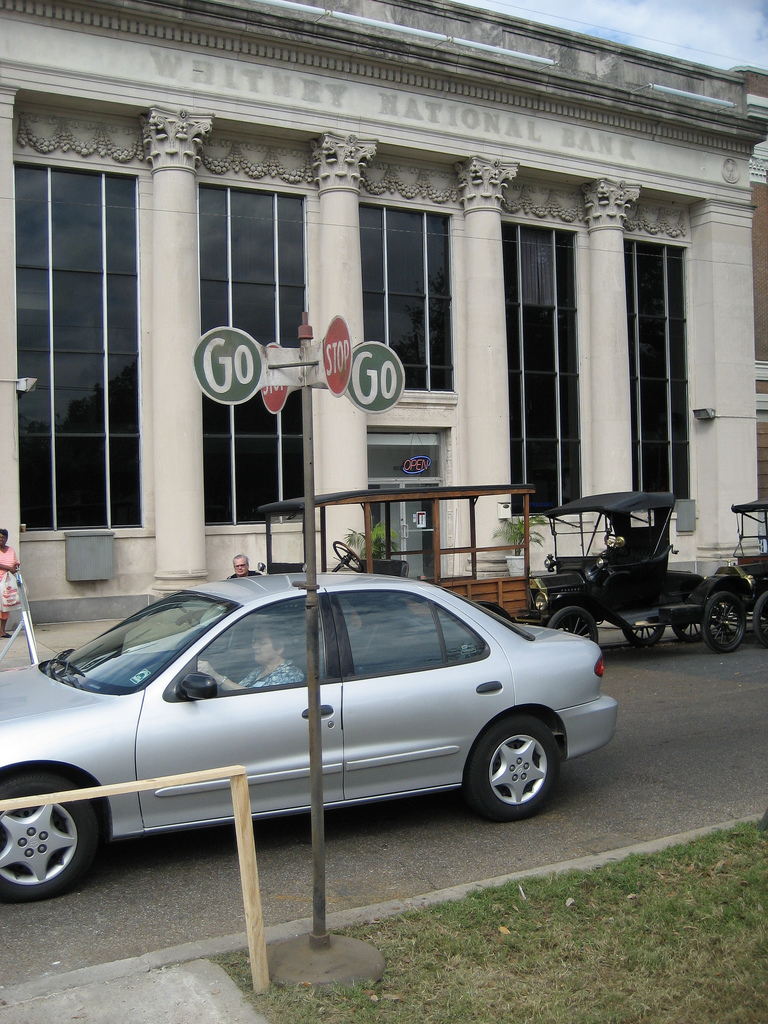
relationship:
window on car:
[437, 601, 490, 673] [9, 569, 641, 901]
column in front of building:
[448, 168, 541, 572] [7, 7, 766, 639]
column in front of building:
[578, 183, 656, 547] [7, 7, 766, 639]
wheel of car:
[4, 764, 110, 900] [9, 569, 641, 901]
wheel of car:
[475, 698, 569, 818] [7, 564, 626, 924]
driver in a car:
[190, 617, 328, 700] [4, 559, 586, 901]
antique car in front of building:
[542, 469, 683, 608] [61, 340, 640, 651]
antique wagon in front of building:
[300, 483, 551, 607] [86, 240, 624, 403]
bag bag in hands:
[1, 516, 44, 704] [3, 443, 90, 708]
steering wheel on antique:
[317, 531, 371, 568] [253, 484, 537, 619]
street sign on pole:
[325, 333, 376, 380] [293, 471, 327, 574]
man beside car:
[208, 555, 273, 596] [38, 619, 546, 901]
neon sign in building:
[387, 442, 458, 485] [0, 0, 766, 622]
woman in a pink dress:
[0, 510, 41, 639] [1, 543, 14, 575]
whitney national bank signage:
[145, 81, 636, 159] [260, 154, 516, 264]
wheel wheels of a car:
[463, 710, 561, 822] [5, 690, 503, 895]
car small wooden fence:
[0, 573, 618, 901] [218, 849, 273, 948]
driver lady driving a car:
[197, 611, 305, 691] [7, 592, 532, 922]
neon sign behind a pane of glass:
[402, 455, 432, 475] [353, 423, 449, 485]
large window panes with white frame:
[519, 284, 580, 531] [497, 320, 517, 486]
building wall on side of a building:
[0, 2, 766, 623] [218, 310, 597, 377]